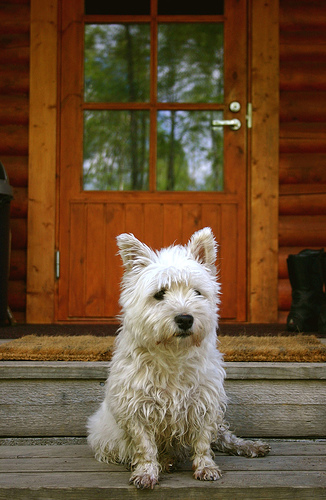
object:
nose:
[172, 313, 194, 331]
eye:
[191, 287, 201, 297]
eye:
[152, 286, 166, 300]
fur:
[155, 333, 204, 348]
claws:
[129, 470, 230, 490]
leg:
[191, 426, 240, 483]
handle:
[209, 117, 241, 130]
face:
[109, 224, 229, 349]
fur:
[121, 361, 182, 410]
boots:
[281, 250, 323, 335]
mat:
[6, 329, 315, 359]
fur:
[143, 367, 196, 401]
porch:
[4, 324, 315, 495]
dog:
[74, 218, 280, 487]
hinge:
[50, 245, 64, 284]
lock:
[211, 100, 245, 132]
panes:
[82, 23, 225, 191]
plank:
[280, 183, 325, 210]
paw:
[125, 472, 160, 492]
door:
[48, 0, 254, 317]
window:
[158, 108, 224, 190]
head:
[108, 221, 226, 351]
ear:
[112, 226, 154, 262]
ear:
[179, 219, 225, 266]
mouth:
[171, 326, 195, 340]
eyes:
[151, 280, 207, 301]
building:
[5, 10, 325, 324]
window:
[81, 22, 151, 105]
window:
[154, 1, 226, 18]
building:
[2, 54, 325, 361]